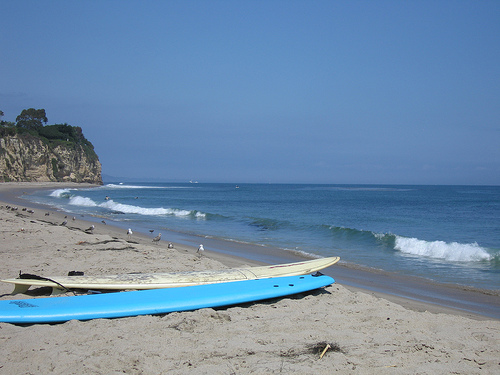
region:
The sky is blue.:
[6, 3, 448, 101]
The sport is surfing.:
[11, 20, 478, 352]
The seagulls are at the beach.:
[8, 188, 247, 275]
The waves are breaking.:
[253, 199, 496, 264]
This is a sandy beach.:
[307, 302, 433, 341]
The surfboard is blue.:
[6, 284, 276, 321]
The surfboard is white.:
[13, 241, 350, 285]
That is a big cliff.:
[0, 132, 110, 190]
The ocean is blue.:
[203, 183, 483, 245]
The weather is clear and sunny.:
[5, 38, 491, 363]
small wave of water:
[124, 192, 265, 262]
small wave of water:
[84, 180, 208, 251]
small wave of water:
[53, 121, 214, 251]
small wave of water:
[97, 168, 244, 330]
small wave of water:
[145, 212, 217, 266]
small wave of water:
[107, 144, 188, 239]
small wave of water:
[160, 184, 250, 299]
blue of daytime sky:
[264, 15, 384, 89]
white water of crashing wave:
[382, 226, 485, 264]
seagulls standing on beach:
[77, 212, 211, 258]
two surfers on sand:
[102, 247, 345, 322]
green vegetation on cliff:
[58, 129, 104, 162]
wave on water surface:
[300, 215, 372, 244]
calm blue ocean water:
[403, 194, 470, 226]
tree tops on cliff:
[18, 96, 50, 122]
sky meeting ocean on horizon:
[398, 175, 446, 197]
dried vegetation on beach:
[303, 337, 352, 361]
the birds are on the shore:
[72, 206, 209, 263]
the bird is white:
[193, 229, 211, 268]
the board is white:
[17, 240, 344, 286]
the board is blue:
[8, 266, 348, 325]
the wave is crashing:
[342, 207, 482, 264]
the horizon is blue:
[278, 105, 444, 153]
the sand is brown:
[344, 305, 447, 362]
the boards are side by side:
[7, 245, 353, 326]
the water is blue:
[326, 181, 452, 214]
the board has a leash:
[22, 265, 57, 285]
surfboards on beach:
[2, 243, 355, 340]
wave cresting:
[370, 221, 493, 282]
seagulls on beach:
[21, 193, 213, 256]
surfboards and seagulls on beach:
[0, 174, 375, 328]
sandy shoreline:
[7, 149, 478, 352]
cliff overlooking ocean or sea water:
[21, 115, 139, 202]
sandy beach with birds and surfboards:
[17, 166, 487, 361]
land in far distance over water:
[22, 115, 444, 262]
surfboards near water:
[2, 190, 462, 345]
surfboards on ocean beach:
[14, 166, 467, 343]